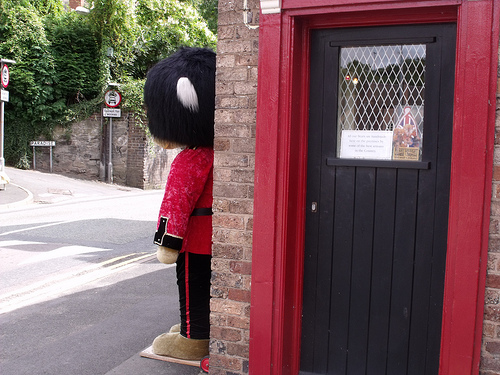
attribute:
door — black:
[276, 10, 460, 373]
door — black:
[248, 12, 475, 372]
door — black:
[285, 21, 453, 370]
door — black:
[288, 14, 434, 373]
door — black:
[291, 13, 461, 363]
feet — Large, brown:
[154, 321, 208, 360]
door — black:
[301, 25, 454, 373]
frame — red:
[247, 0, 497, 372]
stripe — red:
[182, 252, 188, 337]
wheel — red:
[200, 354, 210, 371]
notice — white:
[340, 127, 395, 158]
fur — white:
[176, 75, 199, 110]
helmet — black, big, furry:
[142, 47, 215, 146]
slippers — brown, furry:
[152, 322, 207, 358]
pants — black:
[175, 251, 210, 339]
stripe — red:
[183, 250, 188, 336]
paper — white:
[336, 128, 398, 162]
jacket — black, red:
[148, 143, 217, 260]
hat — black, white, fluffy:
[141, 42, 221, 154]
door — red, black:
[250, 2, 497, 372]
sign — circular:
[89, 54, 150, 183]